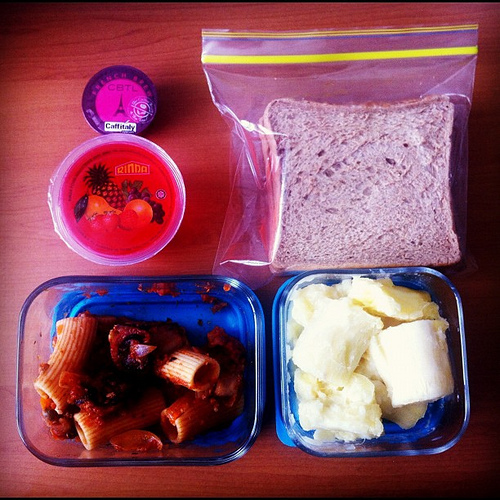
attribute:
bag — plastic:
[254, 98, 465, 277]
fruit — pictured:
[72, 163, 166, 232]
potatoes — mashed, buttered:
[287, 278, 458, 449]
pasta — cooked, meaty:
[34, 316, 247, 451]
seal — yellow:
[203, 44, 479, 65]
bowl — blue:
[271, 270, 451, 448]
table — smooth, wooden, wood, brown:
[2, 4, 497, 499]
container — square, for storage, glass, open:
[17, 274, 267, 468]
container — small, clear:
[279, 264, 472, 457]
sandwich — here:
[259, 98, 462, 278]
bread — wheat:
[260, 96, 462, 271]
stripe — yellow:
[203, 44, 477, 67]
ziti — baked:
[37, 310, 98, 411]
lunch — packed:
[22, 26, 476, 467]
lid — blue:
[266, 277, 448, 448]